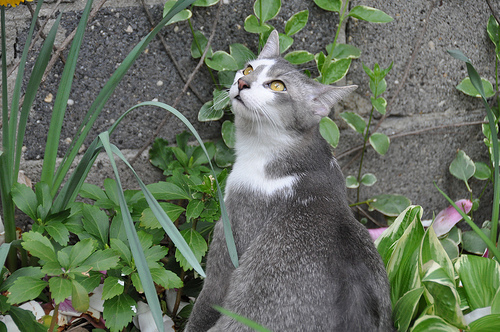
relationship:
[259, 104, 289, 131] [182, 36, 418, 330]
whiskers of cat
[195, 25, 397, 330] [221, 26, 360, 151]
cat has head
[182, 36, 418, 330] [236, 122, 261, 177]
cat has white patch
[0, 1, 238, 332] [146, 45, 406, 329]
grasses bends over to cat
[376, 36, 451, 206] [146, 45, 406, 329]
concrete block behind cat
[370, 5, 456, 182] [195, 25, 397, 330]
wall behind cat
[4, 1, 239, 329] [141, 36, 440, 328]
grasses are behind cat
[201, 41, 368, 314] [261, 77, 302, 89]
cat has eyes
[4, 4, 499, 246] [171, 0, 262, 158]
wall has ivy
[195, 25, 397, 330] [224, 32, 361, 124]
cat has face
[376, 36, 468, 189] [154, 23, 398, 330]
concrete block behind cat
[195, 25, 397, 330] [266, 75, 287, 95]
cat has eye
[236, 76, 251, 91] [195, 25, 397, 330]
nose of cat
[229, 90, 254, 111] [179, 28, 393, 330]
mouth of cat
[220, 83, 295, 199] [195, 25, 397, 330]
fur on cat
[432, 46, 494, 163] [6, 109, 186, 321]
leaves wall on leaves wall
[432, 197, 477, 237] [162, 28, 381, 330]
bud by cat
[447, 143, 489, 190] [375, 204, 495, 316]
leaves of garden plant